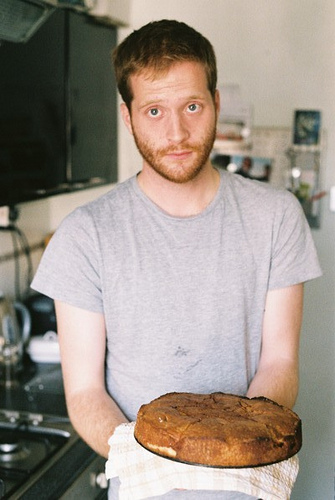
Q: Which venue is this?
A: This is a kitchen.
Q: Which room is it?
A: It is a kitchen.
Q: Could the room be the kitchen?
A: Yes, it is the kitchen.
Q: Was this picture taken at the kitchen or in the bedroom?
A: It was taken at the kitchen.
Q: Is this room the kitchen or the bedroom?
A: It is the kitchen.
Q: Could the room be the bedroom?
A: No, it is the kitchen.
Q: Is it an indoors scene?
A: Yes, it is indoors.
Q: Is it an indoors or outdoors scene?
A: It is indoors.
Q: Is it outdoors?
A: No, it is indoors.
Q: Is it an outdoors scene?
A: No, it is indoors.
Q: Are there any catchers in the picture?
A: No, there are no catchers.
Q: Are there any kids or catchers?
A: No, there are no catchers or kids.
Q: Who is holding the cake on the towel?
A: The man is holding the cake.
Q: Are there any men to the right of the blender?
A: Yes, there is a man to the right of the blender.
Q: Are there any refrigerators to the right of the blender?
A: No, there is a man to the right of the blender.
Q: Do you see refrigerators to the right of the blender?
A: No, there is a man to the right of the blender.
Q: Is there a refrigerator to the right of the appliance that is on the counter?
A: No, there is a man to the right of the blender.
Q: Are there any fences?
A: No, there are no fences.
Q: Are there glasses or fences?
A: No, there are no fences or glasses.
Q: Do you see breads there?
A: Yes, there is a bread.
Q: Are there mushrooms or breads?
A: Yes, there is a bread.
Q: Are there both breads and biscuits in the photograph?
A: No, there is a bread but no biscuits.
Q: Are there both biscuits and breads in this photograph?
A: No, there is a bread but no biscuits.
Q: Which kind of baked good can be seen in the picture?
A: The baked good is a bread.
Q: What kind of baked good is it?
A: The food is a bread.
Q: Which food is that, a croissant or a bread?
A: That is a bread.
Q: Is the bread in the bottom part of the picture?
A: Yes, the bread is in the bottom of the image.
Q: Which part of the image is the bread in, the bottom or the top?
A: The bread is in the bottom of the image.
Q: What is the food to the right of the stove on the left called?
A: The food is a bread.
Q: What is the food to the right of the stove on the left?
A: The food is a bread.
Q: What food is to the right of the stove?
A: The food is a bread.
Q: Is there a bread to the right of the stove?
A: Yes, there is a bread to the right of the stove.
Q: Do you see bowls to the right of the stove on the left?
A: No, there is a bread to the right of the stove.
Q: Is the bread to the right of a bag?
A: No, the bread is to the right of the stove.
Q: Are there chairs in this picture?
A: No, there are no chairs.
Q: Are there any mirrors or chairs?
A: No, there are no chairs or mirrors.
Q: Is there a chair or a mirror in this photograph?
A: No, there are no chairs or mirrors.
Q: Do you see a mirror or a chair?
A: No, there are no chairs or mirrors.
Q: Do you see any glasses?
A: No, there are no glasses.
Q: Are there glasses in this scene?
A: No, there are no glasses.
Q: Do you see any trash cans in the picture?
A: No, there are no trash cans.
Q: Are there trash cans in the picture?
A: No, there are no trash cans.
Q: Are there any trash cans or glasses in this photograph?
A: No, there are no trash cans or glasses.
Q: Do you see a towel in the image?
A: Yes, there is a towel.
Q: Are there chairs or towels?
A: Yes, there is a towel.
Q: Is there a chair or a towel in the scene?
A: Yes, there is a towel.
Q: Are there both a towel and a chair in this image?
A: No, there is a towel but no chairs.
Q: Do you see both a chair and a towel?
A: No, there is a towel but no chairs.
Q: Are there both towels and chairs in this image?
A: No, there is a towel but no chairs.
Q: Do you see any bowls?
A: No, there are no bowls.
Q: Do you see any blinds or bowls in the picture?
A: No, there are no bowls or blinds.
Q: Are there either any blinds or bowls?
A: No, there are no bowls or blinds.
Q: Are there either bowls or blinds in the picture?
A: No, there are no bowls or blinds.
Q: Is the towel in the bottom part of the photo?
A: Yes, the towel is in the bottom of the image.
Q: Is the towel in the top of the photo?
A: No, the towel is in the bottom of the image.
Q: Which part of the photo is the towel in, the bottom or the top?
A: The towel is in the bottom of the image.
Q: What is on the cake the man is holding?
A: The towel is on the cake.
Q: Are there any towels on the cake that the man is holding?
A: Yes, there is a towel on the cake.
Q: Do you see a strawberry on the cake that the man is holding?
A: No, there is a towel on the cake.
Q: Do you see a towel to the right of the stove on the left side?
A: Yes, there is a towel to the right of the stove.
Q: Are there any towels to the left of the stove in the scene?
A: No, the towel is to the right of the stove.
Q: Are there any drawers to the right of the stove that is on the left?
A: No, there is a towel to the right of the stove.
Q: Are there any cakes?
A: Yes, there is a cake.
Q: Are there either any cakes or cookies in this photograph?
A: Yes, there is a cake.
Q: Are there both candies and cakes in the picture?
A: No, there is a cake but no candies.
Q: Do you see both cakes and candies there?
A: No, there is a cake but no candies.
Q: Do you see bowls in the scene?
A: No, there are no bowls.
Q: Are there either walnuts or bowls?
A: No, there are no bowls or walnuts.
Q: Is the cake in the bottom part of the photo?
A: Yes, the cake is in the bottom of the image.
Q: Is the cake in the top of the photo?
A: No, the cake is in the bottom of the image.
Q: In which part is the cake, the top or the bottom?
A: The cake is in the bottom of the image.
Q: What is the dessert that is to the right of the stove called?
A: The dessert is a cake.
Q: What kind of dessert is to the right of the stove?
A: The dessert is a cake.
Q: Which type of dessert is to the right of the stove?
A: The dessert is a cake.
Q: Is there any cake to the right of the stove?
A: Yes, there is a cake to the right of the stove.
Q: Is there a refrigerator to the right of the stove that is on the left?
A: No, there is a cake to the right of the stove.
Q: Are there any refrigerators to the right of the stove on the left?
A: No, there is a cake to the right of the stove.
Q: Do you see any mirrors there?
A: No, there are no mirrors.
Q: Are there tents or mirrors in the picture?
A: No, there are no mirrors or tents.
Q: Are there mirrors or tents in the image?
A: No, there are no mirrors or tents.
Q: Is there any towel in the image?
A: Yes, there is a towel.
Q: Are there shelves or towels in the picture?
A: Yes, there is a towel.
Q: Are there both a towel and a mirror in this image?
A: No, there is a towel but no mirrors.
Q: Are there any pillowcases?
A: No, there are no pillowcases.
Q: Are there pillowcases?
A: No, there are no pillowcases.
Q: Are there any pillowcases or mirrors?
A: No, there are no pillowcases or mirrors.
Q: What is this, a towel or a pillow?
A: This is a towel.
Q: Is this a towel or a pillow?
A: This is a towel.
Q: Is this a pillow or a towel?
A: This is a towel.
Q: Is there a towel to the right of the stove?
A: Yes, there is a towel to the right of the stove.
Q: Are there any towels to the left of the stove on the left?
A: No, the towel is to the right of the stove.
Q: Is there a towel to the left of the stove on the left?
A: No, the towel is to the right of the stove.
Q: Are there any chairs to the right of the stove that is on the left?
A: No, there is a towel to the right of the stove.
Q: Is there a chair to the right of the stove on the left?
A: No, there is a towel to the right of the stove.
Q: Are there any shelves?
A: No, there are no shelves.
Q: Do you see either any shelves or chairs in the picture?
A: No, there are no shelves or chairs.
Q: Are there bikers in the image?
A: No, there are no bikers.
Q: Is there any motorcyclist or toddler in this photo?
A: No, there are no bikers or toddlers.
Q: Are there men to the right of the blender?
A: Yes, there is a man to the right of the blender.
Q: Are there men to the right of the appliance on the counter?
A: Yes, there is a man to the right of the blender.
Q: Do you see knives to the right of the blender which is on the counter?
A: No, there is a man to the right of the blender.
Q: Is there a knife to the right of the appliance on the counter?
A: No, there is a man to the right of the blender.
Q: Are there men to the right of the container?
A: Yes, there is a man to the right of the container.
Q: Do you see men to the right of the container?
A: Yes, there is a man to the right of the container.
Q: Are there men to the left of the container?
A: No, the man is to the right of the container.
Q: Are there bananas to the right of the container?
A: No, there is a man to the right of the container.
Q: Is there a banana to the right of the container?
A: No, there is a man to the right of the container.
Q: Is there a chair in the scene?
A: No, there are no chairs.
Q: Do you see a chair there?
A: No, there are no chairs.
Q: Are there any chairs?
A: No, there are no chairs.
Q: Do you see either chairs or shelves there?
A: No, there are no chairs or shelves.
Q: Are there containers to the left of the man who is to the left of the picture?
A: Yes, there is a container to the left of the man.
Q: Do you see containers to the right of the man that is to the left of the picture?
A: No, the container is to the left of the man.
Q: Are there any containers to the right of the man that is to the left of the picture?
A: No, the container is to the left of the man.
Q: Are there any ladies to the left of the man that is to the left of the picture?
A: No, there is a container to the left of the man.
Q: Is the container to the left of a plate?
A: No, the container is to the left of the man.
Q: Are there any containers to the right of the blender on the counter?
A: Yes, there is a container to the right of the blender.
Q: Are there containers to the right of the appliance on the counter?
A: Yes, there is a container to the right of the blender.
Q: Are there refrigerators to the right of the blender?
A: No, there is a container to the right of the blender.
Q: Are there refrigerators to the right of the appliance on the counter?
A: No, there is a container to the right of the blender.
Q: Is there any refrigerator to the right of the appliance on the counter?
A: No, there is a container to the right of the blender.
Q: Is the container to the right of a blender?
A: Yes, the container is to the right of a blender.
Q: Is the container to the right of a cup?
A: No, the container is to the right of a blender.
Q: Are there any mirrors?
A: No, there are no mirrors.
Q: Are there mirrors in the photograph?
A: No, there are no mirrors.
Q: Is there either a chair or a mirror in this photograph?
A: No, there are no mirrors or chairs.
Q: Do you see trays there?
A: No, there are no trays.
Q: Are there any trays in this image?
A: No, there are no trays.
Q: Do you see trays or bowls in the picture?
A: No, there are no trays or bowls.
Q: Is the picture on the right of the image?
A: Yes, the picture is on the right of the image.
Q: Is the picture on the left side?
A: No, the picture is on the right of the image.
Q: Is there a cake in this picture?
A: Yes, there is a cake.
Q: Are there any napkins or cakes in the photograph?
A: Yes, there is a cake.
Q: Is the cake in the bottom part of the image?
A: Yes, the cake is in the bottom of the image.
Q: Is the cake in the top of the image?
A: No, the cake is in the bottom of the image.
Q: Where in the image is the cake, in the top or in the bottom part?
A: The cake is in the bottom of the image.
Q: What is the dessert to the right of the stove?
A: The dessert is a cake.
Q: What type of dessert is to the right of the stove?
A: The dessert is a cake.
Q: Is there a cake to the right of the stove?
A: Yes, there is a cake to the right of the stove.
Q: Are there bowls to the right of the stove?
A: No, there is a cake to the right of the stove.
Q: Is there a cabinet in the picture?
A: Yes, there is a cabinet.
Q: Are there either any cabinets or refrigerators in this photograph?
A: Yes, there is a cabinet.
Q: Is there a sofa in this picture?
A: No, there are no sofas.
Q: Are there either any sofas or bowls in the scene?
A: No, there are no sofas or bowls.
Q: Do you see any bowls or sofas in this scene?
A: No, there are no sofas or bowls.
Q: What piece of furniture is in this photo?
A: The piece of furniture is a cabinet.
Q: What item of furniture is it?
A: The piece of furniture is a cabinet.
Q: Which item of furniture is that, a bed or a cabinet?
A: That is a cabinet.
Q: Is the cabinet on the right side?
A: No, the cabinet is on the left of the image.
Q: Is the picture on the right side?
A: Yes, the picture is on the right of the image.